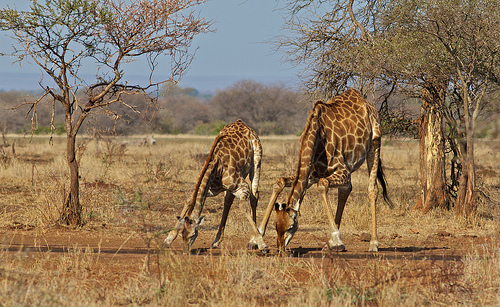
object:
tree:
[0, 81, 499, 136]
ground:
[0, 131, 499, 306]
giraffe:
[243, 87, 395, 255]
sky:
[0, 1, 466, 102]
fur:
[274, 210, 289, 236]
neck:
[188, 156, 216, 214]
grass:
[0, 132, 499, 306]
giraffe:
[150, 117, 270, 257]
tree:
[0, 0, 222, 230]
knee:
[270, 182, 286, 193]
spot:
[227, 149, 239, 158]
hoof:
[256, 246, 271, 257]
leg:
[231, 175, 264, 247]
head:
[175, 212, 206, 255]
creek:
[0, 239, 459, 261]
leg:
[250, 175, 297, 245]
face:
[270, 209, 296, 257]